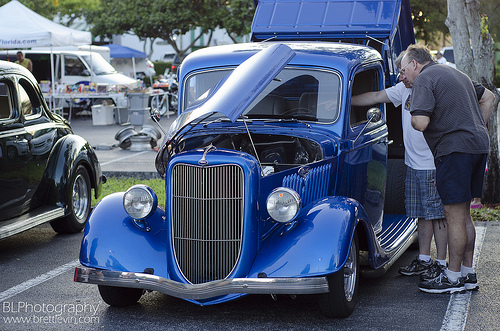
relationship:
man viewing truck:
[401, 42, 491, 295] [70, 1, 423, 318]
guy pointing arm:
[352, 51, 449, 281] [350, 83, 401, 108]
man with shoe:
[401, 42, 491, 295] [419, 274, 467, 295]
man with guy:
[401, 42, 491, 295] [352, 51, 449, 281]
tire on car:
[48, 163, 93, 235] [0, 61, 107, 253]